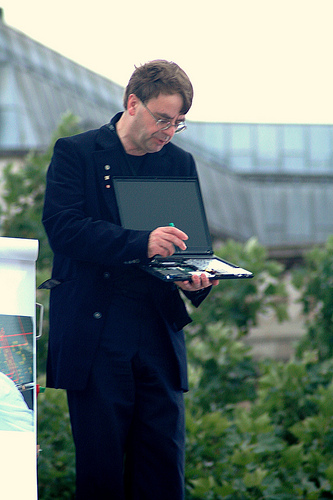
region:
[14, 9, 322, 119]
light of daytime sky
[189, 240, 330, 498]
green leaves of trees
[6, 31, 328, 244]
glass panes on structure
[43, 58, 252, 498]
man in suit with laptop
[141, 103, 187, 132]
glasses on man's face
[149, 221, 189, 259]
tool in man's hand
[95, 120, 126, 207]
pins on jacket lapel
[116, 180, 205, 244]
screen of open laptop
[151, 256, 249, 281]
hand under laptop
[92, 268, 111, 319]
two buttons on jacket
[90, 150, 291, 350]
an open laptop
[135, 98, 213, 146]
glasses on his face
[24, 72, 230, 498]
a man in all black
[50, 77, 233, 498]
a man working on a laptop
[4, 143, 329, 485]
green leaves behind man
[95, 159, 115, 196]
three pins on his jacket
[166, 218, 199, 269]
a green tool in hand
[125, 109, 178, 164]
five o'clock shadow on face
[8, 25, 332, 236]
a building behind the man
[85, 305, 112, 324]
a button on his jacket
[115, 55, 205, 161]
the head of a man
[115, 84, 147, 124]
the ear of a man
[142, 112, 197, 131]
the eyes of a man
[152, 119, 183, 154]
the nose of a man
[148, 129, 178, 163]
the mouth of a man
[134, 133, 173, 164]
the chin of a man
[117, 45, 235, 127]
the hair of a man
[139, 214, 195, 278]
the hand of a man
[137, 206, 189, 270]
the fingers of a man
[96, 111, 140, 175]
the neck of a man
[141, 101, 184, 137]
eye glasses worn by man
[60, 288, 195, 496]
black pants worn by the man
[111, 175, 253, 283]
open black laptop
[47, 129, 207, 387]
black sportcoat worn by man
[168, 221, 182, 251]
green marker in man's hand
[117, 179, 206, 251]
screen of the black laptop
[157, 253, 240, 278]
buttons on the keyboard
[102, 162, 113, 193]
pins on man's lapel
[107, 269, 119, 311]
black buttons on the sportcoat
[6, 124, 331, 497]
trees behind the man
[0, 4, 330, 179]
light gray sky over slanted roofing panels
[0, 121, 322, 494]
trees in front of building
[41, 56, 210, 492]
man dressed in dark outfit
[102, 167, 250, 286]
man looking at laptop from behind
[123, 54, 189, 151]
eyeglasses and stubble on face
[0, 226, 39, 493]
rolled pad of paper showing sleeve and dotted background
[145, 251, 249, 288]
hand supporting bottom of laptop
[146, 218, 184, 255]
fingers holding green marker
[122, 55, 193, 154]
head down with lips apart